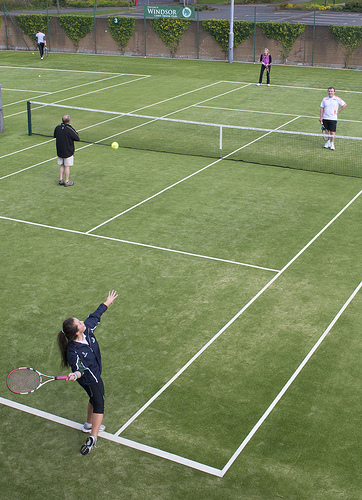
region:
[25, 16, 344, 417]
There are five people visible in the photo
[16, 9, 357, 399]
The people are playing tennis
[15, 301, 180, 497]
The girl has a racquet in her hand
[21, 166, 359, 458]
The turf is green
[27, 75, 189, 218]
the tennis ball is green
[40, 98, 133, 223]
The man has a black jacket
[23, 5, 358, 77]
There is a parking lot above the tennis field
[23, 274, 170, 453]
The girl is wearing a blue jacket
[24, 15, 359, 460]
There are two people wearing shorts in the photo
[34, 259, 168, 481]
The girl is wearing sneakers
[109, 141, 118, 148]
Green tennis ball in the air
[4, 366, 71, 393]
Red and white tennis racket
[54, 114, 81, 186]
Older man on a tennis court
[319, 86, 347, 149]
Middle aged man on a tennis court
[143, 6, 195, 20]
Green and white building sign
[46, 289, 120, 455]
Young woman playing tennis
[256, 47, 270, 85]
Older woman playing tennis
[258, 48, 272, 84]
Woman waiting for a tennis serve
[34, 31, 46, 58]
Young man walking towards a ball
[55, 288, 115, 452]
Young girl preparing to hit the ball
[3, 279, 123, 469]
a woman about to serve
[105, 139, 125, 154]
a high toss for the serve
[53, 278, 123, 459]
a woman play tennis on a cool day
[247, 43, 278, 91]
a woman ready to receive serve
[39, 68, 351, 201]
the men doubles partners of the women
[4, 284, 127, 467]
a woman committing a foot fault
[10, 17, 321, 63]
ivy growing on a fence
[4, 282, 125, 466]
a woman with a pony tail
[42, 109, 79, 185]
a man with a pony tail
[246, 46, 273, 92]
a woman wearing lavender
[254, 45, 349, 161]
People on court playing tennis.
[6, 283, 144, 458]
Woman hitting tennis ball.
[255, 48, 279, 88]
Tennis player dressed in black and pink tennis outfit.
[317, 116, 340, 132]
Man dressed in black shorts.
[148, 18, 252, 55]
Green vines growing on wall behind tennis court.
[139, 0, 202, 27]
Green and white sign on wall behind tennis court.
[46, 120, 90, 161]
Man dressed in black jacket.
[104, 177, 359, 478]
White markings on tennis court.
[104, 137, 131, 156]
Yellow tennis ball in air.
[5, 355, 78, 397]
Woman holding pink and white tennis racket.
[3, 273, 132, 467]
woman swinging a tennis racket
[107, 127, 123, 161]
tennis ball flying through the air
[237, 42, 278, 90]
woman wearing pink and black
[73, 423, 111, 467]
white shoes with black bottoms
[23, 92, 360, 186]
tennis net centered on the court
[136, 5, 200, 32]
green sign with the word "windsor"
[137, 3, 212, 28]
white letters on a green background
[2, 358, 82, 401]
pink tennis racket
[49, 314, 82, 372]
brown hair in a ponytail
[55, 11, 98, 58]
plants hanging over the wall